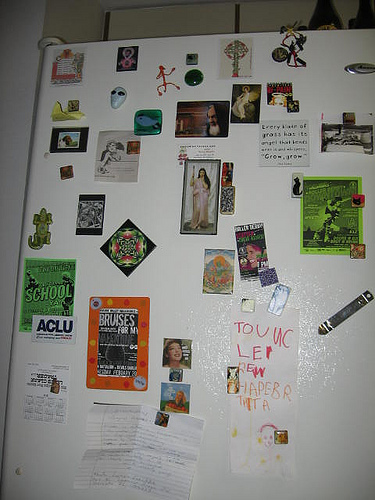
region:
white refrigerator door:
[1, 34, 373, 499]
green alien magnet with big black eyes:
[103, 83, 126, 115]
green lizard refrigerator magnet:
[24, 208, 63, 250]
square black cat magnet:
[276, 170, 305, 204]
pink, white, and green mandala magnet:
[89, 217, 158, 278]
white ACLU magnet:
[23, 310, 78, 348]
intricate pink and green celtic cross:
[212, 37, 254, 83]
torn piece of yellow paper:
[46, 98, 91, 121]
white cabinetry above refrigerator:
[91, 0, 368, 41]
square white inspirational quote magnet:
[252, 117, 311, 170]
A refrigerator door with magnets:
[3, 22, 372, 492]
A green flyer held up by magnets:
[287, 167, 373, 270]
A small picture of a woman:
[154, 338, 196, 369]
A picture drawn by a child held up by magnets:
[228, 292, 295, 470]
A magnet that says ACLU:
[24, 310, 77, 350]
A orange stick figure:
[150, 61, 180, 102]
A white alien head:
[108, 81, 130, 113]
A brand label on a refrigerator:
[339, 60, 372, 79]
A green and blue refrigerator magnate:
[128, 106, 170, 140]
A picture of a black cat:
[287, 168, 307, 199]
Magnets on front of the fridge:
[96, 88, 180, 131]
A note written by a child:
[220, 297, 317, 498]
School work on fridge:
[75, 398, 231, 483]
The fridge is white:
[317, 358, 373, 437]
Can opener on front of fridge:
[310, 281, 374, 341]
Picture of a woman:
[184, 153, 219, 232]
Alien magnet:
[105, 82, 131, 115]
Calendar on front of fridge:
[17, 352, 109, 437]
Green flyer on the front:
[299, 168, 369, 270]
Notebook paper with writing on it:
[87, 415, 159, 498]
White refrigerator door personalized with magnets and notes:
[13, 23, 368, 497]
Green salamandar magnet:
[27, 206, 54, 252]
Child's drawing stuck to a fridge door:
[227, 300, 303, 486]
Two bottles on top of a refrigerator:
[310, 0, 374, 35]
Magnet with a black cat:
[289, 171, 305, 201]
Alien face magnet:
[107, 85, 130, 111]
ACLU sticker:
[30, 313, 77, 346]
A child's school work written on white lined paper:
[69, 405, 208, 498]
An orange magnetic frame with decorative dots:
[88, 296, 152, 392]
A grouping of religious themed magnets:
[175, 37, 256, 233]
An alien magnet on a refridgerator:
[104, 85, 128, 109]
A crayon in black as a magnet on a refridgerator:
[316, 286, 373, 334]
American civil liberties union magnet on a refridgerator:
[30, 310, 80, 346]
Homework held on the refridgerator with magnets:
[228, 297, 301, 482]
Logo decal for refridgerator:
[340, 59, 371, 88]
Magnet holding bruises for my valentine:
[88, 294, 151, 390]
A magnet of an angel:
[230, 81, 263, 128]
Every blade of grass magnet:
[254, 117, 311, 167]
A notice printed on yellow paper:
[294, 175, 360, 259]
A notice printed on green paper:
[21, 253, 78, 330]